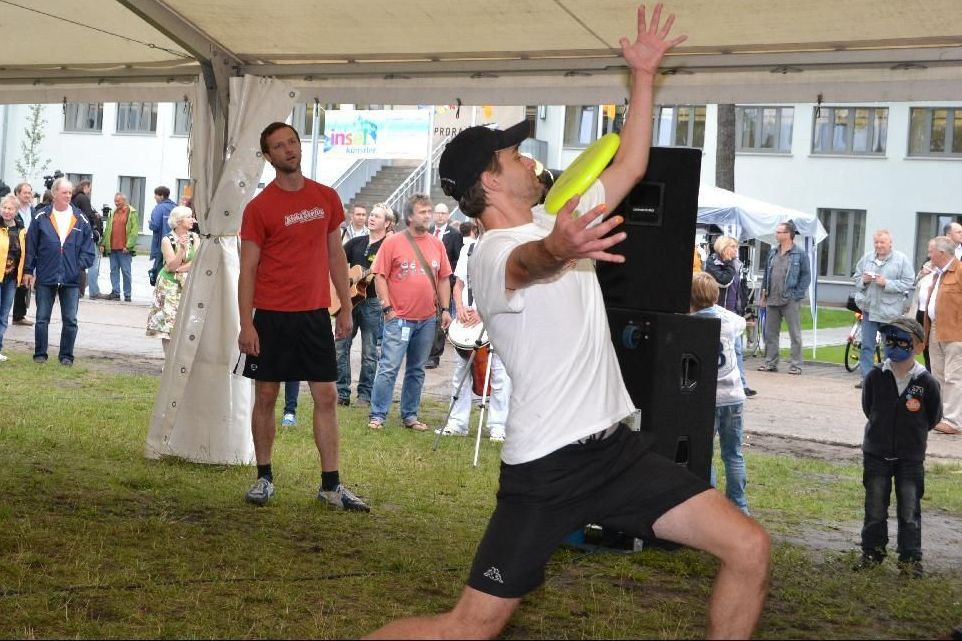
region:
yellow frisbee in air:
[542, 129, 621, 214]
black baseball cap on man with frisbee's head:
[434, 117, 538, 198]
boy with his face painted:
[859, 313, 946, 583]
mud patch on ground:
[768, 495, 960, 573]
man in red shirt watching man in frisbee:
[234, 120, 372, 515]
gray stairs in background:
[342, 158, 423, 215]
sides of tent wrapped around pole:
[140, 71, 302, 461]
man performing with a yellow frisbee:
[359, 3, 772, 639]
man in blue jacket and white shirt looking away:
[19, 170, 98, 366]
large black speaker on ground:
[605, 309, 719, 550]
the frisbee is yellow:
[543, 118, 622, 221]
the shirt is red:
[253, 184, 342, 324]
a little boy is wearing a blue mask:
[837, 301, 959, 410]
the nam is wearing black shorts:
[230, 272, 319, 399]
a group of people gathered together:
[2, 177, 204, 240]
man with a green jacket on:
[119, 179, 146, 279]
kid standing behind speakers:
[688, 275, 763, 459]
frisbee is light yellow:
[547, 127, 628, 210]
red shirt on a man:
[244, 185, 347, 311]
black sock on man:
[316, 471, 343, 492]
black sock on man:
[249, 463, 277, 482]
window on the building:
[805, 204, 865, 285]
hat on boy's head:
[863, 310, 926, 338]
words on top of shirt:
[273, 204, 330, 223]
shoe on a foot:
[321, 490, 366, 509]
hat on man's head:
[437, 121, 538, 195]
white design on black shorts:
[471, 563, 512, 583]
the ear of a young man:
[452, 164, 515, 212]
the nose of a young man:
[510, 143, 558, 175]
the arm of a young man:
[430, 175, 671, 335]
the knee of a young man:
[616, 429, 853, 602]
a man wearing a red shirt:
[176, 110, 386, 498]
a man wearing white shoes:
[197, 442, 434, 546]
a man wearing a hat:
[423, 69, 590, 211]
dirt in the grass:
[89, 487, 165, 515]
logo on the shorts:
[467, 562, 509, 589]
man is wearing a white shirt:
[506, 320, 611, 403]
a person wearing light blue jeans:
[717, 412, 748, 498]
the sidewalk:
[782, 372, 825, 428]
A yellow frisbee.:
[539, 126, 621, 215]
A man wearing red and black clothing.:
[231, 108, 375, 516]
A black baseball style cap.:
[435, 106, 542, 196]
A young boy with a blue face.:
[857, 305, 946, 572]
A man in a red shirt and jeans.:
[370, 191, 451, 442]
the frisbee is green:
[537, 124, 630, 222]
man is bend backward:
[352, 3, 795, 633]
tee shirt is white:
[456, 181, 646, 472]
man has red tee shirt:
[363, 186, 461, 433]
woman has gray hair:
[152, 194, 208, 296]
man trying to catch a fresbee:
[421, 0, 765, 368]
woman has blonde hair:
[702, 221, 755, 285]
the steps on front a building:
[330, 141, 430, 214]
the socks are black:
[247, 456, 345, 494]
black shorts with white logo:
[424, 397, 723, 610]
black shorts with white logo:
[454, 396, 705, 607]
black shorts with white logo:
[427, 396, 705, 603]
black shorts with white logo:
[443, 386, 724, 610]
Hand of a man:
[551, 187, 634, 274]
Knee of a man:
[733, 500, 781, 585]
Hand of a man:
[226, 323, 269, 368]